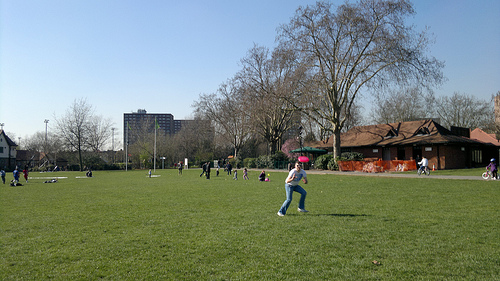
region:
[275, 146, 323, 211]
man in blue jeans awaiting a red frisbee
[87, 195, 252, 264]
green grass of a field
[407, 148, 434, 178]
person in white shirt riding a bycycle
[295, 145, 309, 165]
red frisbee floating through the air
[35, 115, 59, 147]
light pole in the distance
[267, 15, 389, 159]
tree with grey trunk and sparse leafs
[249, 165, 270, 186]
person sitting on the ground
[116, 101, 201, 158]
building with lots of windows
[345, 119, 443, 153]
brown roof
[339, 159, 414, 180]
red fencing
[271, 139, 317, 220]
man poised to catch red frisbee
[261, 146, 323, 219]
red frisbee in air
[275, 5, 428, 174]
mostly bare tree over one story building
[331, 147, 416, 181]
orange construction netting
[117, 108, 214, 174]
multi-story building in the distance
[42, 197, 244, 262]
large flat stretch of short green grass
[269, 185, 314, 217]
legs wearing jeans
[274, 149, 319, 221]
man with right arm bent to catch frisbee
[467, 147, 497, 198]
helmet-clad bicyclist in distance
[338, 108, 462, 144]
building with brown rood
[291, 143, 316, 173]
a frisbee flying through the air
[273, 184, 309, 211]
a pair of blue jeans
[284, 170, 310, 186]
a white t-shirt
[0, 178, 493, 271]
an open grassy field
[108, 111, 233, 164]
a large office building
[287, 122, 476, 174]
a short brown building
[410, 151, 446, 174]
a man on a bicycle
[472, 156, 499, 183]
a little girl next to a bicycle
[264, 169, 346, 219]
a man about to catch a frisbee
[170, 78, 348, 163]
a row of trees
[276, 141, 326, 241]
man catching pink frisbee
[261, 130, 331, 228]
One man one frisbee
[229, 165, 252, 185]
Two children play field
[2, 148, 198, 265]
Park area all sports.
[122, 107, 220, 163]
Office building high distance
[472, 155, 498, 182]
Safety helmet bicyclist sidewalk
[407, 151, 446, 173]
Person healthy walk daily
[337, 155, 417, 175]
Construction done front building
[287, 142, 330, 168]
Building entrance green awning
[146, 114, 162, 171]
Flag pole flag flying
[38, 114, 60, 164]
Park lighting evening play